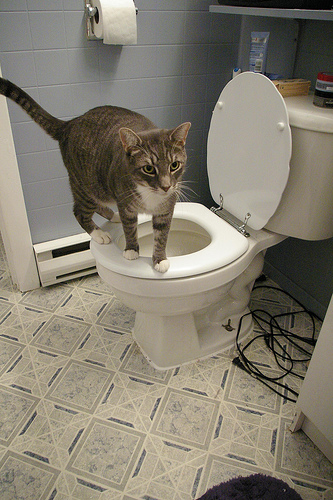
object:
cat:
[0, 80, 192, 275]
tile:
[65, 413, 148, 500]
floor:
[0, 247, 332, 500]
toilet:
[89, 70, 333, 372]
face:
[140, 148, 185, 196]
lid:
[206, 71, 291, 232]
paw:
[152, 254, 170, 273]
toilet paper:
[91, 0, 140, 49]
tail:
[0, 77, 63, 143]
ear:
[118, 127, 141, 153]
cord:
[233, 285, 317, 405]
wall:
[0, 0, 240, 247]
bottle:
[313, 71, 333, 109]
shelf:
[208, 0, 333, 23]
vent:
[33, 235, 98, 291]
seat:
[89, 201, 249, 280]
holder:
[85, 3, 138, 18]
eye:
[144, 165, 155, 175]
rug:
[196, 471, 305, 500]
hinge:
[239, 213, 252, 236]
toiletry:
[312, 75, 333, 110]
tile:
[34, 48, 71, 88]